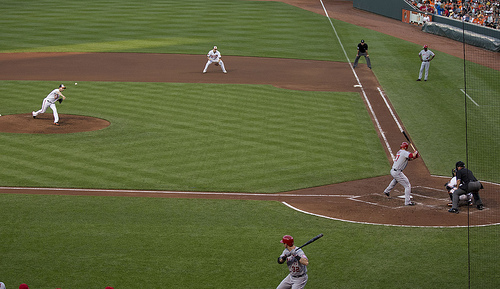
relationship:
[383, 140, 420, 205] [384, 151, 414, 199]
man in uniform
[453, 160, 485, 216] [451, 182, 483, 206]
umpire wearing pants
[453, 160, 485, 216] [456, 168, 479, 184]
umpire wearing shirt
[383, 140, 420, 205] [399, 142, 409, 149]
man wearing helmet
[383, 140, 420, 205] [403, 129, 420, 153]
man swinging bat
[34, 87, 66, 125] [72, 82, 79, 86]
pitcher threw ball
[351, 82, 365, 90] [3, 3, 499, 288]
base on field.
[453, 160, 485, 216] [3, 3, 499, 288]
umpire on field.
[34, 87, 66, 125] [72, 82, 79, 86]
pitcher throws ball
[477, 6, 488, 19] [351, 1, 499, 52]
people sitting in stands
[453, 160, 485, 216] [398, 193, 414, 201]
umpire behind base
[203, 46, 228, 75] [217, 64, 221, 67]
man wearing mitt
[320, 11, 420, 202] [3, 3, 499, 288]
line on field.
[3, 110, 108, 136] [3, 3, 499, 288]
pitcher mound on field.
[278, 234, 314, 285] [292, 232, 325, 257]
man swinging bat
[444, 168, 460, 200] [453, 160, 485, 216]
catcher in front of umpire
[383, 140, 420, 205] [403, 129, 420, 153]
man holding bat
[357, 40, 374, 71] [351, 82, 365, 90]
umpire behind base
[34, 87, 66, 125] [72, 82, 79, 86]
pitcher throwing ball